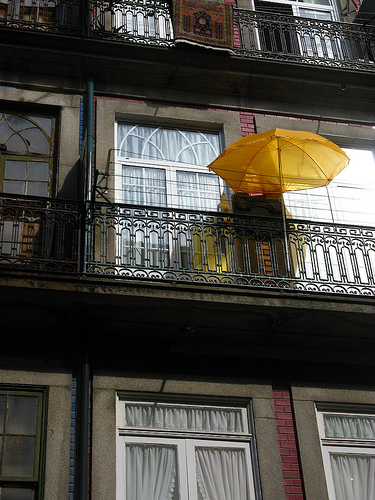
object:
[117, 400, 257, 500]
window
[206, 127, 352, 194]
umbrella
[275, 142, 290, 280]
pole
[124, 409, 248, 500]
curtain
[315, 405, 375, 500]
windows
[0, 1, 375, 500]
building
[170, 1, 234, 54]
rug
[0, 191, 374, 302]
railing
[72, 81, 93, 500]
pipe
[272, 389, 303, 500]
brick